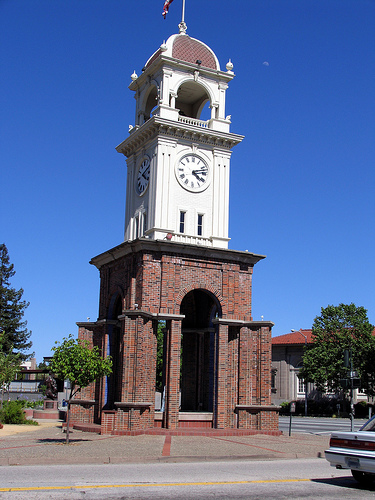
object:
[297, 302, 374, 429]
tree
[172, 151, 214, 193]
clock face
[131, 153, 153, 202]
clock face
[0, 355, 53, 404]
building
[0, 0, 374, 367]
sky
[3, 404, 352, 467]
corner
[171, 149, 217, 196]
clock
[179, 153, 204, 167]
numerals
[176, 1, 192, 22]
pole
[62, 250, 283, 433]
base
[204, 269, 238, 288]
brick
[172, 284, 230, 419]
doorway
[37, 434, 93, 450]
shadow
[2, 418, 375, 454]
ground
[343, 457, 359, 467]
license plate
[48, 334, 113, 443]
bush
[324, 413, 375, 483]
car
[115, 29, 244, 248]
tower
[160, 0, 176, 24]
flag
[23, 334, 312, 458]
forefront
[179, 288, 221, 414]
opening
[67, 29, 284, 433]
structure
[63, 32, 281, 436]
building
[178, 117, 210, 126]
railing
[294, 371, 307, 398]
window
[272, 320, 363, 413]
building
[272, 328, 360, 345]
roof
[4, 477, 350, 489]
line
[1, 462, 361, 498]
road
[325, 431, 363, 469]
rear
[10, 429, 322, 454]
sidewalk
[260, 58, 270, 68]
moon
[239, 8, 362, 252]
sky